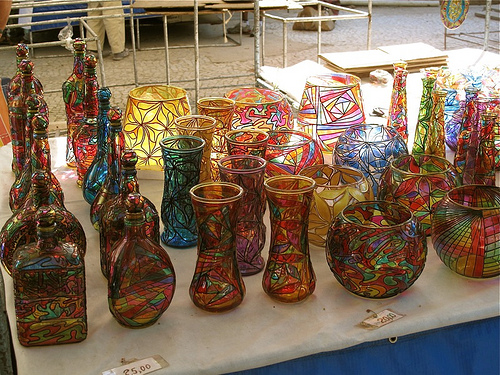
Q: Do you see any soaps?
A: No, there are no soaps.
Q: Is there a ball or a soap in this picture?
A: No, there are no soaps or balls.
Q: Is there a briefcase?
A: No, there are no briefcases.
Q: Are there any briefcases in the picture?
A: No, there are no briefcases.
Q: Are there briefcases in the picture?
A: No, there are no briefcases.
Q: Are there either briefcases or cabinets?
A: No, there are no briefcases or cabinets.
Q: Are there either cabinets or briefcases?
A: No, there are no briefcases or cabinets.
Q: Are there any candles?
A: No, there are no candles.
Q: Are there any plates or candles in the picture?
A: No, there are no candles or plates.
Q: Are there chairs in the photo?
A: No, there are no chairs.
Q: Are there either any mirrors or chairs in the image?
A: No, there are no chairs or mirrors.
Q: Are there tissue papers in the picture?
A: No, there are no tissue papers.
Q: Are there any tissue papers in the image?
A: No, there are no tissue papers.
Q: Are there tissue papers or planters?
A: No, there are no tissue papers or planters.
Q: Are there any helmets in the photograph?
A: No, there are no helmets.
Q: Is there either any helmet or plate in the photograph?
A: No, there are no helmets or plates.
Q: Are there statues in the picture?
A: No, there are no statues.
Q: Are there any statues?
A: No, there are no statues.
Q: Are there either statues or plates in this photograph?
A: No, there are no statues or plates.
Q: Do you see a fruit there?
A: No, there are no fruits.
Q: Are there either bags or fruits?
A: No, there are no fruits or bags.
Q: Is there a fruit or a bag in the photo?
A: No, there are no fruits or bags.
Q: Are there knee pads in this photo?
A: No, there are no knee pads.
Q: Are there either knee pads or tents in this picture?
A: No, there are no knee pads or tents.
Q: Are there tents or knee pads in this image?
A: No, there are no knee pads or tents.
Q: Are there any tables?
A: Yes, there is a table.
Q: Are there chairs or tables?
A: Yes, there is a table.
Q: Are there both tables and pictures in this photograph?
A: No, there is a table but no pictures.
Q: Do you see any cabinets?
A: No, there are no cabinets.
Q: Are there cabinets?
A: No, there are no cabinets.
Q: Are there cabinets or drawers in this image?
A: No, there are no cabinets or drawers.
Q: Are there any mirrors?
A: No, there are no mirrors.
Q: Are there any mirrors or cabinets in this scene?
A: No, there are no mirrors or cabinets.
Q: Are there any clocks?
A: No, there are no clocks.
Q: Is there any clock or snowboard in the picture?
A: No, there are no clocks or snowboards.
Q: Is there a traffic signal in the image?
A: No, there are no traffic lights.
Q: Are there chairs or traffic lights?
A: No, there are no traffic lights or chairs.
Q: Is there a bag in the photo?
A: No, there are no bags.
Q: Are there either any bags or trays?
A: No, there are no bags or trays.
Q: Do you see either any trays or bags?
A: No, there are no bags or trays.